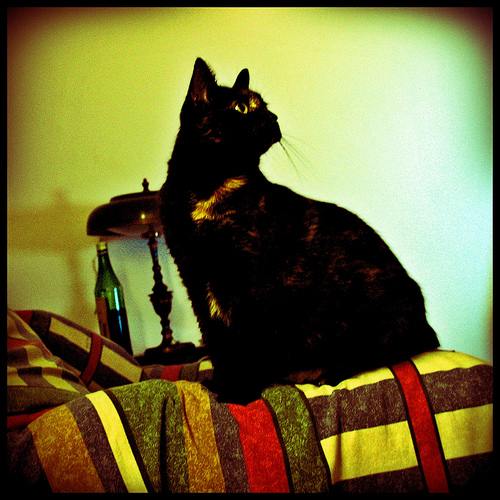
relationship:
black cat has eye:
[158, 57, 440, 405] [230, 96, 251, 118]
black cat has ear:
[158, 57, 440, 405] [230, 67, 250, 91]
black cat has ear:
[158, 57, 440, 405] [183, 57, 218, 102]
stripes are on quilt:
[28, 389, 148, 492] [0, 324, 494, 497]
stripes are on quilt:
[294, 347, 491, 491] [0, 324, 494, 497]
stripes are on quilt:
[51, 313, 143, 382] [0, 324, 494, 497]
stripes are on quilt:
[8, 329, 80, 396] [0, 324, 494, 497]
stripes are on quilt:
[225, 394, 289, 492] [0, 324, 494, 497]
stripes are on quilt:
[5, 329, 474, 488] [0, 324, 494, 497]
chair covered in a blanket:
[82, 159, 344, 407] [10, 309, 498, 498]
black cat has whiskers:
[158, 57, 440, 405] [277, 127, 309, 172]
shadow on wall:
[10, 187, 110, 330] [8, 9, 492, 359]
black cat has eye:
[158, 57, 440, 405] [224, 92, 274, 117]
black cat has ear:
[158, 57, 440, 405] [233, 63, 259, 93]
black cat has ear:
[158, 57, 440, 405] [182, 51, 222, 97]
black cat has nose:
[158, 57, 440, 405] [264, 113, 279, 122]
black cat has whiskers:
[158, 57, 440, 405] [264, 124, 323, 181]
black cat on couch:
[158, 57, 440, 405] [7, 306, 497, 499]